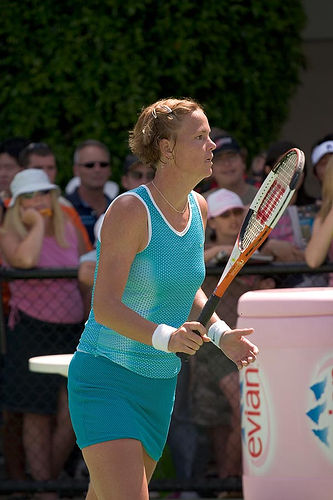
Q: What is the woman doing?
A: Playing tennis.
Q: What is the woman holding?
A: A tennis racket.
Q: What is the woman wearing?
A: A short skirt.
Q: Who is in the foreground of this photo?
A: A woman in blue.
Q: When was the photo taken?
A: During a tennis match.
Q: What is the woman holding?
A: A tennis racket.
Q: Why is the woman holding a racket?
A: She's playing tennis.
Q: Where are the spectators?
A: Behind the fence.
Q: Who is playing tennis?
A: Lindsay Davenport.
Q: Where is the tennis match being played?
A: On an outdoor court.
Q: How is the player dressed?
A: In a blue tank top and skirt.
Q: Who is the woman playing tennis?
A: Lindsay Davenport.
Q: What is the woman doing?
A: Playing tennis.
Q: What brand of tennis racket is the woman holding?
A: A Wilson tennis racket.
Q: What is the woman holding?
A: A red and black tennis racket.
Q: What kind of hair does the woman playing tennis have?
A: Short blonde hair.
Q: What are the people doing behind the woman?
A: They are spectators watching the match.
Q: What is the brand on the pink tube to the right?
A: Evian.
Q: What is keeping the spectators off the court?
A: A chainlink fence.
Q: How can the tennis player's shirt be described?
A: A tank top with white trim around the neck and arms.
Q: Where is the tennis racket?
A: Lady's hand.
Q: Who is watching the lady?
A: A crowd.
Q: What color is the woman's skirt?
A: Blue.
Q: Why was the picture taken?
A: To capture her playing tennis.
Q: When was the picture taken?
A: In the daytime.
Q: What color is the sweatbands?
A: White.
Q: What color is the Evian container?
A: Pink.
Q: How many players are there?
A: 1.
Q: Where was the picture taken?
A: On a tennis court.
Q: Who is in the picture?
A: A tennis player and spectators.